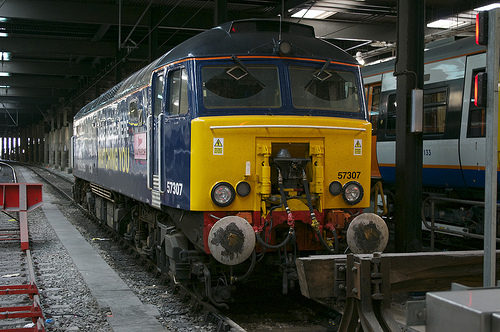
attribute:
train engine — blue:
[65, 12, 389, 301]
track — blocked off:
[0, 157, 80, 329]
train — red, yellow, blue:
[66, 30, 347, 273]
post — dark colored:
[387, 16, 434, 256]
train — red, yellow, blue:
[120, 95, 180, 176]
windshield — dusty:
[192, 54, 380, 128]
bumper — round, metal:
[192, 167, 406, 315]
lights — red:
[210, 177, 235, 207]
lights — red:
[342, 179, 362, 203]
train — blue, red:
[63, 15, 390, 307]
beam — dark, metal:
[389, 7, 442, 274]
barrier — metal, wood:
[286, 208, 499, 328]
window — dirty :
[301, 62, 356, 102]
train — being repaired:
[57, 9, 411, 297]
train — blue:
[31, 16, 380, 328]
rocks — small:
[24, 215, 104, 330]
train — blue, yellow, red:
[145, 70, 380, 272]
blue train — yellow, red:
[66, 16, 388, 313]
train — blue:
[81, 37, 392, 296]